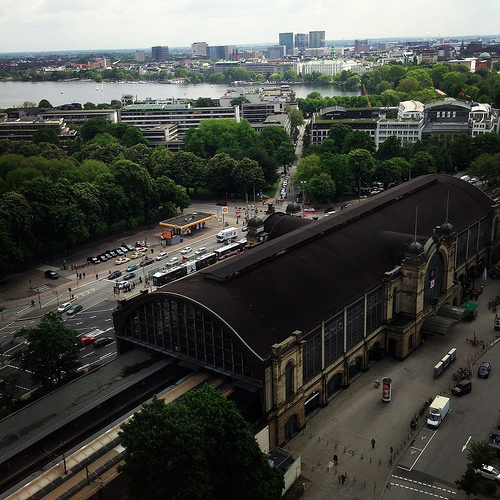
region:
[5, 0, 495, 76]
blue sky over a city skyline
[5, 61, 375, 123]
buildings and trees surrounding water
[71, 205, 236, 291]
cars and buses moving on street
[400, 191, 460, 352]
grand arched entryway with domes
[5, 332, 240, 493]
train rails extending into building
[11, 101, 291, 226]
trees growing in front of low buildings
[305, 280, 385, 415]
large window panels over arches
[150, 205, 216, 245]
flat-roof bus shelter edged in orange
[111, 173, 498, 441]
a bus terminal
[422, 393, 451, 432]
a small white truck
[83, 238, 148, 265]
cars parked in a parking lot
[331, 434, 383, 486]
people walking on the side walk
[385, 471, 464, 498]
a cross walk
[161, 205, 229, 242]
a gas station on the side of the road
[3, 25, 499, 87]
city sky line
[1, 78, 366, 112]
a body of water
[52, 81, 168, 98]
small boats on the water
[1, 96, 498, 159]
buildings with lots of windows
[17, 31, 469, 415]
a picture of a large city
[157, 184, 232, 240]
a gas station in the city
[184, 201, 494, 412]
this is a facility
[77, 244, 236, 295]
traffic on the street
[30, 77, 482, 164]
structues in the area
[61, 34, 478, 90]
this city is very big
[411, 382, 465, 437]
a white truck in the picture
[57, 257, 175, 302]
people and cars on the street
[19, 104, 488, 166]
this metropolitan area is very large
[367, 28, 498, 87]
infrastucture in the background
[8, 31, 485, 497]
view of city from above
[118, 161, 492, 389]
building with rounded roof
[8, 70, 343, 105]
water with boats in it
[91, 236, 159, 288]
street with vehicles in it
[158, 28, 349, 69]
buildings across the water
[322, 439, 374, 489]
people in the road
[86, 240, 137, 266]
vehicles on the lot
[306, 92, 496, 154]
building on the ground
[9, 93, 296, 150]
building on the ground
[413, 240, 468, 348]
entrance to the building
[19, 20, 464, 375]
a very busy scene of a city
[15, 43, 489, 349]
the city is spread out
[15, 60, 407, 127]
a river runs through the city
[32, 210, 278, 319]
traffic is on the street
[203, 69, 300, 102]
a dock area is on the river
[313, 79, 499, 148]
a building in the scene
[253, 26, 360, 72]
skyscrapers in the background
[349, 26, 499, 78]
a section of the city far away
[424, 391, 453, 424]
white truck parked on a road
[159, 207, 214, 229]
rectangular cover over a gas station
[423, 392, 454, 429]
a white box truck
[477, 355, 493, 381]
a black car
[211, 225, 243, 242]
a white truck with blue writing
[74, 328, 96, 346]
a parked red car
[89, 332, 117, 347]
a parked blue car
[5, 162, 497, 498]
a large building with many windows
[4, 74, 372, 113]
a large body of water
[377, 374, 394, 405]
a kiosk with something on it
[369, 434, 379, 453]
a person wearing black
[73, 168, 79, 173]
A green leaf on a plant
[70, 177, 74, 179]
A green leaf on a plant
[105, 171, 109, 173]
A green leaf on a plant